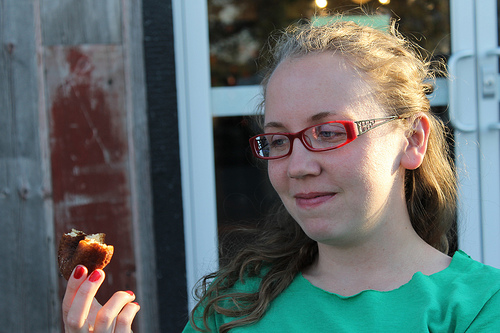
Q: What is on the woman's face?
A: Glasses.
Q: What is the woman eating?
A: Donut.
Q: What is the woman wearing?
A: Shirt.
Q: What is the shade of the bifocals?
A: Red.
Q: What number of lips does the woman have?
A: 2.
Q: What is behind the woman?
A: Window.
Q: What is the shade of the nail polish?
A: Red.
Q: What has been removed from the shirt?
A: A collar.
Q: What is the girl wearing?
A: It's glasses.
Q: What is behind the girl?
A: Glass doors.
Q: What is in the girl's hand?
A: It's food.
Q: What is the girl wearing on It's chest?
A: A blue top.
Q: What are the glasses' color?
A: It's red.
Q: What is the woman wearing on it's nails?
A: It's polish.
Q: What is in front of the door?
A: A woman.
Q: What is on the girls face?
A: Glasses.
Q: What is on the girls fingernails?
A: Polish.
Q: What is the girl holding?
A: Donut.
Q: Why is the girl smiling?
A: Happy.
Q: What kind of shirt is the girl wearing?
A: Blouse.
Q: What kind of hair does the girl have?
A: Blonde.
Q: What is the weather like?
A: Sunny.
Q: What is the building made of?
A: Stone.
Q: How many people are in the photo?
A: One.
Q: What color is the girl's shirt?
A: Green.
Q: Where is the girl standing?
A: In front of doors.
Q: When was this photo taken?
A: In the daytime.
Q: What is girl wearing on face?
A: Glasses.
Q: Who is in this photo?
A: A girl.